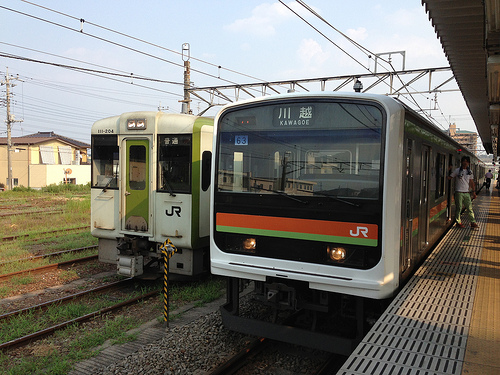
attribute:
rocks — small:
[168, 329, 220, 358]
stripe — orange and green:
[214, 213, 381, 249]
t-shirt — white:
[451, 165, 476, 188]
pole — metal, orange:
[144, 230, 181, 322]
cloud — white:
[287, 21, 485, 159]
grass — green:
[1, 181, 224, 370]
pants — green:
[451, 187, 478, 225]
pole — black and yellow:
[152, 228, 199, 333]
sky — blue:
[0, 0, 492, 157]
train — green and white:
[208, 97, 432, 294]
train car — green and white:
[85, 105, 220, 283]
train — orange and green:
[208, 92, 498, 357]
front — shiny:
[208, 93, 394, 301]